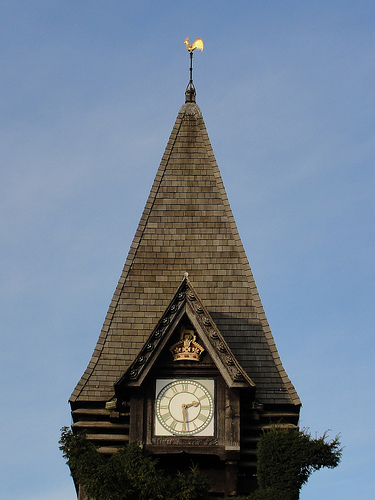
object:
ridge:
[70, 403, 129, 417]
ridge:
[244, 406, 299, 418]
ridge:
[242, 436, 283, 444]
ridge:
[72, 421, 130, 430]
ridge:
[94, 444, 126, 454]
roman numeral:
[180, 382, 187, 391]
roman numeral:
[199, 393, 206, 402]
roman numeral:
[201, 404, 211, 409]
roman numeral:
[197, 414, 206, 421]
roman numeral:
[181, 421, 187, 435]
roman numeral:
[169, 419, 177, 429]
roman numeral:
[160, 412, 170, 421]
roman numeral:
[157, 405, 172, 410]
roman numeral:
[161, 394, 172, 399]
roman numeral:
[170, 383, 177, 393]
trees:
[60, 420, 124, 498]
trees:
[98, 439, 174, 497]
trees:
[172, 462, 215, 498]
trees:
[246, 469, 275, 499]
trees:
[256, 452, 294, 498]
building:
[66, 34, 302, 497]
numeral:
[197, 414, 207, 422]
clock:
[150, 375, 216, 439]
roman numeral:
[192, 384, 198, 395]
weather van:
[179, 33, 203, 53]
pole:
[187, 49, 193, 82]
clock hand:
[181, 402, 186, 434]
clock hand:
[182, 399, 201, 406]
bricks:
[170, 196, 182, 213]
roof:
[65, 84, 321, 434]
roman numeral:
[157, 411, 175, 421]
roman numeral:
[188, 418, 199, 430]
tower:
[68, 35, 302, 498]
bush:
[57, 416, 345, 498]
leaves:
[318, 426, 343, 465]